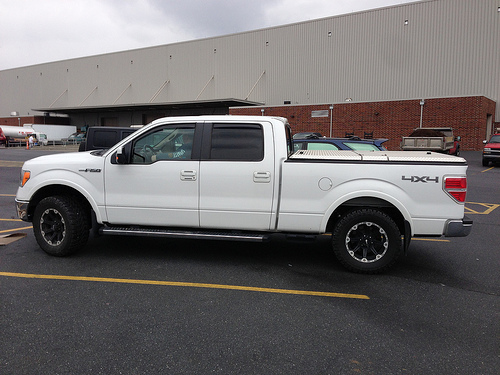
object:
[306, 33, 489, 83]
wall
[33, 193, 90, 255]
tire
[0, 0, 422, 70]
sky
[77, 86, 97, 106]
poles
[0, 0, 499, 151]
building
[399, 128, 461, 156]
truck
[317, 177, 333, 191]
compartment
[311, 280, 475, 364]
asphalt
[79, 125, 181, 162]
black car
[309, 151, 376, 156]
bed cover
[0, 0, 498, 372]
picture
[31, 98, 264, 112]
awning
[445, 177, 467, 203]
light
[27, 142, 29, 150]
cone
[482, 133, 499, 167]
red truck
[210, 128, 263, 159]
window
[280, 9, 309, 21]
gray cloud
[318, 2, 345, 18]
gray cloud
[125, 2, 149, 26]
gray cloud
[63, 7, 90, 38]
gray cloud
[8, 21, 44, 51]
gray cloud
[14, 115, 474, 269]
car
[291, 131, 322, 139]
car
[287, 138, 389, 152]
car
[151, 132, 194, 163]
person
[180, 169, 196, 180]
doorhandle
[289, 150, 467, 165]
bed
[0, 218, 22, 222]
line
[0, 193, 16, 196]
line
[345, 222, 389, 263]
rim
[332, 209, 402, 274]
wheel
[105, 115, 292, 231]
cab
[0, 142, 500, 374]
road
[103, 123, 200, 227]
door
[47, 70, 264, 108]
row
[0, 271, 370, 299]
line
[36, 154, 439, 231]
side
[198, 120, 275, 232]
doors